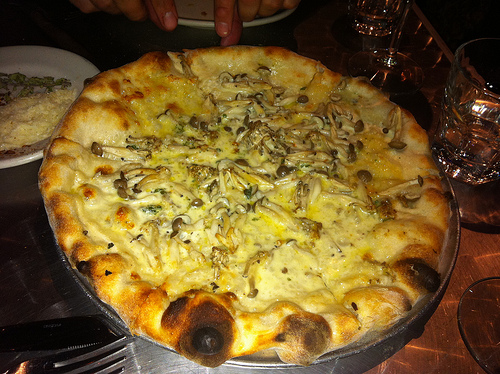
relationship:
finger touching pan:
[210, 9, 242, 45] [52, 45, 462, 366]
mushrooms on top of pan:
[153, 89, 349, 263] [52, 45, 462, 366]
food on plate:
[2, 69, 83, 159] [1, 38, 113, 187]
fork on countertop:
[33, 335, 129, 373] [4, 5, 498, 365]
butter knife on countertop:
[0, 309, 112, 353] [4, 5, 498, 365]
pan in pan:
[52, 45, 462, 366] [37, 34, 451, 372]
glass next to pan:
[428, 49, 498, 209] [52, 45, 462, 366]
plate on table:
[455, 269, 498, 372] [10, 7, 497, 372]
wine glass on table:
[8, 5, 498, 372] [348, 11, 435, 121]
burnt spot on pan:
[159, 282, 240, 367] [52, 45, 462, 366]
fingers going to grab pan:
[115, 5, 264, 45] [52, 45, 462, 366]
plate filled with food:
[1, 38, 113, 187] [2, 69, 83, 159]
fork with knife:
[33, 335, 129, 373] [20, 300, 116, 342]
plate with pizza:
[455, 269, 498, 372] [75, 60, 393, 349]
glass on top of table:
[348, 2, 433, 92] [10, 7, 497, 372]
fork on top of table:
[16, 325, 129, 373] [10, 7, 497, 372]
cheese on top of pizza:
[140, 96, 347, 283] [62, 41, 452, 353]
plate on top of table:
[1, 38, 113, 187] [10, 7, 497, 372]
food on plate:
[2, 69, 83, 159] [0, 33, 101, 185]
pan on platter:
[52, 45, 462, 366] [46, 40, 466, 365]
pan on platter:
[52, 45, 462, 366] [16, 24, 490, 371]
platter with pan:
[46, 40, 466, 365] [52, 45, 462, 366]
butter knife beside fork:
[0, 313, 117, 346] [3, 330, 133, 371]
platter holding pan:
[46, 40, 466, 365] [52, 45, 462, 366]